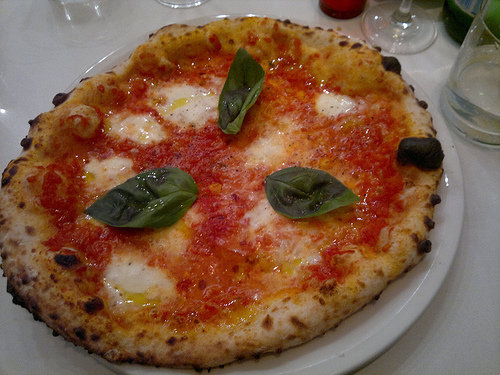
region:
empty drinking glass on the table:
[437, 7, 492, 129]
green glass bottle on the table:
[441, 3, 499, 50]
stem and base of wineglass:
[353, 4, 440, 51]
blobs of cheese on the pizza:
[47, 59, 374, 309]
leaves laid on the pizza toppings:
[72, 59, 374, 236]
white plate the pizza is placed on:
[22, 22, 463, 374]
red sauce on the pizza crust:
[50, 64, 401, 323]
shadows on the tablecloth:
[373, 199, 479, 369]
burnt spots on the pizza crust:
[4, 32, 442, 353]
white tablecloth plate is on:
[5, 2, 498, 374]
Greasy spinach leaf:
[80, 163, 200, 232]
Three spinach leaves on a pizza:
[80, 45, 361, 229]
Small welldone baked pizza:
[0, 16, 445, 368]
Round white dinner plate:
[42, 11, 464, 373]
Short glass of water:
[440, 1, 498, 151]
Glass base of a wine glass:
[360, 1, 437, 56]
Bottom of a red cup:
[314, 0, 369, 22]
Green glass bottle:
[441, 2, 498, 45]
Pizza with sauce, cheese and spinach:
[2, 15, 446, 372]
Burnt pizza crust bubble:
[394, 133, 447, 176]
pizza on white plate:
[3, 14, 448, 373]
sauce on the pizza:
[53, 50, 385, 300]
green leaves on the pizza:
[71, 42, 353, 220]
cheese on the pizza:
[78, 76, 381, 311]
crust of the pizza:
[0, 17, 435, 368]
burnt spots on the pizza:
[5, 13, 436, 355]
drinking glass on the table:
[448, 9, 498, 138]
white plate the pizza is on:
[15, 16, 469, 374]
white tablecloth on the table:
[6, 4, 496, 374]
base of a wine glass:
[366, 4, 434, 56]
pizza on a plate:
[2, 7, 444, 366]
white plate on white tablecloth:
[8, 2, 499, 372]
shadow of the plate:
[366, 153, 485, 371]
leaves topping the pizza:
[58, 52, 364, 234]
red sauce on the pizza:
[40, 46, 396, 303]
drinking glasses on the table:
[362, 4, 495, 151]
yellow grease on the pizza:
[67, 73, 379, 333]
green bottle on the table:
[440, 2, 499, 49]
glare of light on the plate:
[80, 40, 117, 75]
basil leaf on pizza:
[214, 44, 266, 135]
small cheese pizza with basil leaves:
[3, 15, 443, 365]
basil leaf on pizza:
[86, 166, 201, 237]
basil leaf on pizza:
[261, 164, 362, 222]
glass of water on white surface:
[441, 2, 498, 152]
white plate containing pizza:
[39, 34, 464, 374]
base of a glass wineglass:
[360, 2, 436, 57]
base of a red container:
[316, 1, 367, 20]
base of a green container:
[442, 1, 498, 56]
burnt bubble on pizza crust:
[393, 137, 444, 175]